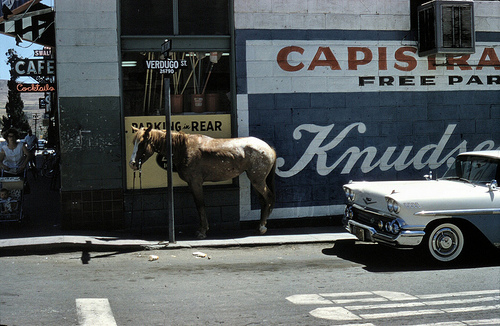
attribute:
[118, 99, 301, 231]
horse — standing, alone, brown, white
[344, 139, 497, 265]
car — white, blue, classic, parked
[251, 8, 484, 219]
wall — white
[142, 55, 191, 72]
sign — promotional, street printed stop, painted, neon, here, gray, black, white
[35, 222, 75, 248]
sidewalk — paved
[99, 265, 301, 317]
street — paved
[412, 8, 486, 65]
air conditioner — mounted, metal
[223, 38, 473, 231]
advertisement — painted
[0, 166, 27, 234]
stroller — pushed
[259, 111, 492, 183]
letter — here, red, white, painted red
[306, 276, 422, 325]
pavement — painted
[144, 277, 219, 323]
road — painted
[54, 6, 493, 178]
building — painted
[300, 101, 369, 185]
writing — white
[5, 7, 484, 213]
building — side , old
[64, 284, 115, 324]
"line — White 